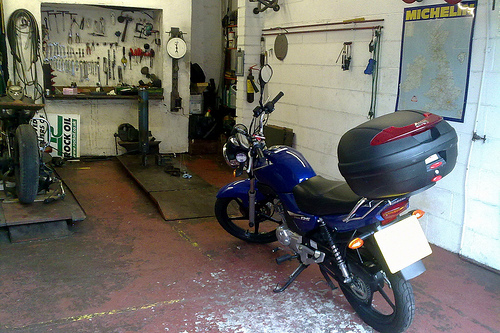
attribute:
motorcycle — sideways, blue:
[215, 91, 459, 332]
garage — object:
[0, 0, 497, 333]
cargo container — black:
[335, 109, 459, 200]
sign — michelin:
[395, 1, 479, 112]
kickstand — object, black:
[262, 249, 318, 296]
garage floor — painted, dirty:
[0, 153, 499, 331]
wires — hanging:
[5, 6, 41, 101]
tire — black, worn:
[11, 123, 40, 207]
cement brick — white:
[305, 85, 351, 111]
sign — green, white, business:
[33, 113, 80, 163]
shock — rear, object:
[314, 219, 354, 285]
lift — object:
[116, 151, 215, 215]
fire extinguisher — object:
[245, 64, 258, 104]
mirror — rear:
[259, 61, 274, 85]